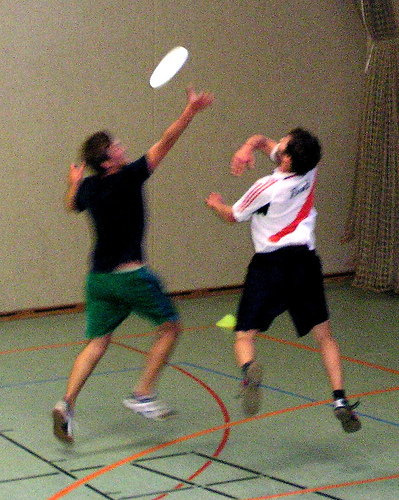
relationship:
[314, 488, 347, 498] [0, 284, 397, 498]
line on floor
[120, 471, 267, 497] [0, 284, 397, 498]
line on floor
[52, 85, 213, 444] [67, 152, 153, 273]
guys wearing shirt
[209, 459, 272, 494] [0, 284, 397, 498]
line on floor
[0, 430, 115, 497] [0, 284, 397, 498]
line on floor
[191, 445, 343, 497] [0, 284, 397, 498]
line on floor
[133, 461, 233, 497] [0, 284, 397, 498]
line on floor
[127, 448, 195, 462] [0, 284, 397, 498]
line on floor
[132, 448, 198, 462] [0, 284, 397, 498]
line on floor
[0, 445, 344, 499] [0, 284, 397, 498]
black line on floor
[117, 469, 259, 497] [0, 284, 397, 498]
line on floor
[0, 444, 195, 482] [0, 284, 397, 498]
line on floor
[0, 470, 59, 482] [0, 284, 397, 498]
line on floor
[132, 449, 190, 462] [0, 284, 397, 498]
line on floor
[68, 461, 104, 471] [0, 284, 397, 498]
line on floor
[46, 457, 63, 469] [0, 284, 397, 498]
line on floor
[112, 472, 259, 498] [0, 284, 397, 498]
line on floor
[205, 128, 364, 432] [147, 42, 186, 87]
guys jumps to get frisbee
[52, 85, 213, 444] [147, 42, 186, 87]
guys jumps to get frisbee